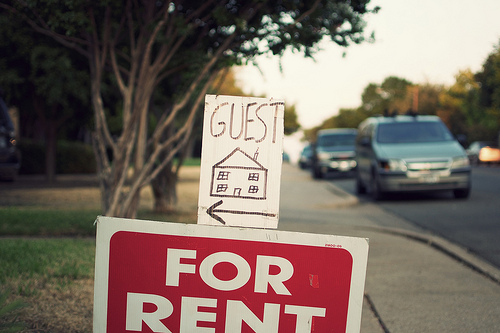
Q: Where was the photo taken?
A: It was taken at the street.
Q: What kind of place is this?
A: It is a street.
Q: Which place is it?
A: It is a street.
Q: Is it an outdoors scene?
A: Yes, it is outdoors.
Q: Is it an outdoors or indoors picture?
A: It is outdoors.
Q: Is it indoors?
A: No, it is outdoors.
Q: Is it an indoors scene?
A: No, it is outdoors.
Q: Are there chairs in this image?
A: No, there are no chairs.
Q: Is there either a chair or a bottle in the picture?
A: No, there are no chairs or bottles.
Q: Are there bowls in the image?
A: No, there are no bowls.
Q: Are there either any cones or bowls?
A: No, there are no bowls or cones.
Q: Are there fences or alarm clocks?
A: No, there are no fences or alarm clocks.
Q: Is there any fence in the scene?
A: No, there are no fences.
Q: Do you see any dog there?
A: No, there are no dogs.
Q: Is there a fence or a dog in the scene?
A: No, there are no dogs or fences.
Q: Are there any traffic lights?
A: No, there are no traffic lights.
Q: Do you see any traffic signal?
A: No, there are no traffic lights.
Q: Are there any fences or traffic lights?
A: No, there are no traffic lights or fences.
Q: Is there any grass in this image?
A: Yes, there is grass.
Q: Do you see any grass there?
A: Yes, there is grass.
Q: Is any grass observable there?
A: Yes, there is grass.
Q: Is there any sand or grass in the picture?
A: Yes, there is grass.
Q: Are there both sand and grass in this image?
A: No, there is grass but no sand.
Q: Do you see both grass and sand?
A: No, there is grass but no sand.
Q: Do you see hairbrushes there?
A: No, there are no hairbrushes.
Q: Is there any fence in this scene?
A: No, there are no fences.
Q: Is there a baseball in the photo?
A: No, there are no baseballs.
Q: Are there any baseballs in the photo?
A: No, there are no baseballs.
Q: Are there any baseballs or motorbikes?
A: No, there are no baseballs or motorbikes.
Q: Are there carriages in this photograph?
A: No, there are no carriages.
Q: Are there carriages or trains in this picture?
A: No, there are no carriages or trains.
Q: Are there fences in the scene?
A: No, there are no fences.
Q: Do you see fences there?
A: No, there are no fences.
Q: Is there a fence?
A: No, there are no fences.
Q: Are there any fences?
A: No, there are no fences.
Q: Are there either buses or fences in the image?
A: No, there are no fences or buses.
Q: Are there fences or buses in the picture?
A: No, there are no fences or buses.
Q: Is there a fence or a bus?
A: No, there are no fences or buses.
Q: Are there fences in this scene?
A: No, there are no fences.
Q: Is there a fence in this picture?
A: No, there are no fences.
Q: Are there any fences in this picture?
A: No, there are no fences.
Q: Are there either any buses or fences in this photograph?
A: No, there are no fences or buses.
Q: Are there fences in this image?
A: No, there are no fences.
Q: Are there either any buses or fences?
A: No, there are no fences or buses.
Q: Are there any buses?
A: No, there are no buses.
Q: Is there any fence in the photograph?
A: No, there are no fences.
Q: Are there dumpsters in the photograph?
A: No, there are no dumpsters.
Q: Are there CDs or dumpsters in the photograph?
A: No, there are no dumpsters or cds.